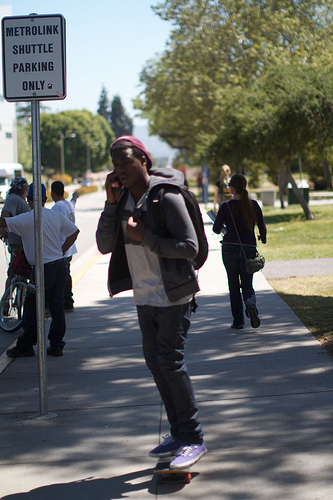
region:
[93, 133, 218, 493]
Young man talking on cell phone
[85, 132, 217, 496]
Man standing on a skateboard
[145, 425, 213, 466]
Blue tennis shoes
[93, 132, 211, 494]
Man holding a backpack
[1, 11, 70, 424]
Sign of a shuttle in the street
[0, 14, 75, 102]
Square traffic sign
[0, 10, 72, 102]
White sign with black border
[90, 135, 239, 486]
Man wearing a red cap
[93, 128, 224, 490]
Man with a gray jacket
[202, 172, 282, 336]
Woman holding folders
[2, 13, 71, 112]
White traffic sign on sidewalk.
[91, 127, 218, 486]
A boy riding skateboard.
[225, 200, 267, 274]
Girl carrying purse on shoulder.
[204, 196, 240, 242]
Girl carrying books on left arm.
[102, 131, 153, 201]
Boy talking on phone.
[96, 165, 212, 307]
Boy wearing gray hooded jacket.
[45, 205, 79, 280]
Man standing with hand on hip.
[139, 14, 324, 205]
Tree growing next to sidewalk.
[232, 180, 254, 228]
A girl's long ponytail.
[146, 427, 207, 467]
Boy wearing blue tennis shoes.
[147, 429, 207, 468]
PURPLE AND WHITE SNEAKERS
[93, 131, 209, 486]
BOY ON SKATEBOARD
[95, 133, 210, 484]
BOY ON SKATEBOARD ON HIS PHONE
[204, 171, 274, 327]
LADY WALKING ALONG SIDE WALK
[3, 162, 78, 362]
THREE GUYS STANDING ON CURB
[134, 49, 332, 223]
BIG GREE TREE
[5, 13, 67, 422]
BUS PARKING SIGN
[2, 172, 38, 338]
MAN ON BICYCLE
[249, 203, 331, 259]
PATCH OF GREEN GRASS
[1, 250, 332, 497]
PAVED SIDE WALK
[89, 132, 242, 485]
Man skateboarding in the street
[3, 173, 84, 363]
Tree men standing in the street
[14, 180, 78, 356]
Two men wearing white t-shits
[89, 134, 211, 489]
Man talking by phone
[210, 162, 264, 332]
Two woman walking down the streert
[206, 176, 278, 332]
Woman with a pony tail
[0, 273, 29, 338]
Wheel of a bike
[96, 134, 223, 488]
Young man with a backpack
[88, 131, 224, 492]
Man wearing bluejeans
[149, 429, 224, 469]
Purple tennis shoes with laces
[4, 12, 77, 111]
a white sign with black lettering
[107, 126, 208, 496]
a man on a skateboard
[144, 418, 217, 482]
person in blue shoes on a skateboard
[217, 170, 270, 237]
woman with hair in a pony tail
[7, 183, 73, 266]
a man wearing a white teeshirt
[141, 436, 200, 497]
skateboard with a red wheel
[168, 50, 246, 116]
deciduous tree with green leaves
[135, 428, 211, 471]
blue skating shoes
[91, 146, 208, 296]
man in a grey sweatshirt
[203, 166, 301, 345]
a woman walking down the sidewalk